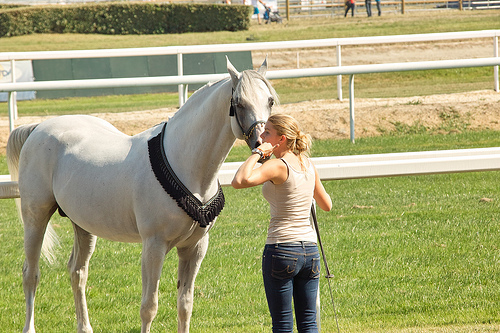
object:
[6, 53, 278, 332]
horse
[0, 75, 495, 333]
ground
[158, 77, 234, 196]
neck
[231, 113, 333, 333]
lady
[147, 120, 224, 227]
bridle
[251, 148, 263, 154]
watch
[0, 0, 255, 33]
bushes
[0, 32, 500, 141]
rail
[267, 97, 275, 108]
eye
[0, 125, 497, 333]
grass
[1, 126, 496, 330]
field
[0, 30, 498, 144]
barricade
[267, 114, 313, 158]
hair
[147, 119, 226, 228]
black collar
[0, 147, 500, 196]
path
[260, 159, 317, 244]
tank top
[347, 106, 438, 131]
dirt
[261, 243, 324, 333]
blue jeans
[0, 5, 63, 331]
left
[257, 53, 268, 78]
ear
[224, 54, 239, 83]
ear